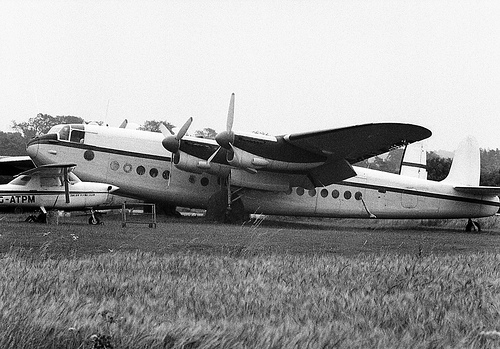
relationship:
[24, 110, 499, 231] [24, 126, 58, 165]
plane has nose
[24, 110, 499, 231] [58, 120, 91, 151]
plane has cockpit window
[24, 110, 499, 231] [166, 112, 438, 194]
plane has sidewing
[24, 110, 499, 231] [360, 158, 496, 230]
plane has tail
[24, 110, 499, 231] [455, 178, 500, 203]
plane has tailwing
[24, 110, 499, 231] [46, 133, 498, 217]
plane has stripe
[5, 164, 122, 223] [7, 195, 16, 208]
plane has letter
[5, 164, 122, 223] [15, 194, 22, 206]
plane has letter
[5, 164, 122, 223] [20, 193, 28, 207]
plane has letter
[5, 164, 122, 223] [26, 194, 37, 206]
plane has letter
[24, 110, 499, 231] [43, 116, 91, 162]
plane has cockpit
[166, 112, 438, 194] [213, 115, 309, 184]
sidewing has motor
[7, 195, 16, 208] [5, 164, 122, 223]
letter on plane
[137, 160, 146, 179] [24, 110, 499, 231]
window on plane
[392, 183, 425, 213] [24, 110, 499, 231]
door on plane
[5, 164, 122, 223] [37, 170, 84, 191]
plane has cockpit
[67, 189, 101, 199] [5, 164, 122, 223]
numbers on plane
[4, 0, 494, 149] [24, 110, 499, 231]
sky above plane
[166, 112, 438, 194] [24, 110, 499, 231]
sidewing on plane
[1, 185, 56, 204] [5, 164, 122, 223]
sidewing on plane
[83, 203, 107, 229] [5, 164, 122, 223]
wheel on plane